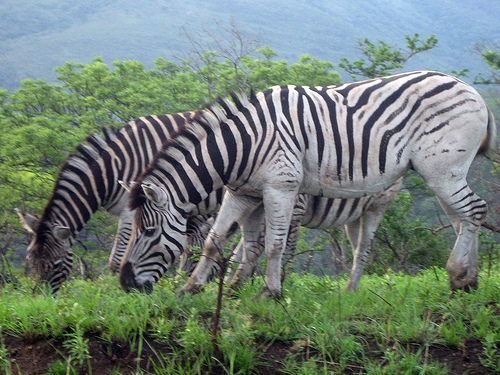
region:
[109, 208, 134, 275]
the black and white leg of a zebra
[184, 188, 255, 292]
the black and white leg of a zebra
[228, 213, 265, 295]
the black and white leg of a zebra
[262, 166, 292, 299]
the black and white leg of a zebra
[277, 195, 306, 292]
the black and white leg of a zebra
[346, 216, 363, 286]
the black and white leg of a zebra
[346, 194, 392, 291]
the black and white leg of a zebra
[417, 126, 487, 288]
the black and white leg of a zebra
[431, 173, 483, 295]
the black and white leg of a zebra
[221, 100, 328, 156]
stripes on a zebra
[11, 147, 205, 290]
two zebra heads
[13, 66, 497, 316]
two zebras eating grass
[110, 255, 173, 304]
zebra mouth grazing in a field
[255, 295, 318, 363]
grass growing in a field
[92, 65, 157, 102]
green leaves on a tree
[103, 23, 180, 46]
grass on the side of a mountain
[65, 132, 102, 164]
striped mane of a zebra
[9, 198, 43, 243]
ear on a horse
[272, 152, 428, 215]
the nearly unstriped belly of a mountain zebra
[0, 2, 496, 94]
a densely treed mountainside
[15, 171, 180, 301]
three zebra grazing in the tall weeds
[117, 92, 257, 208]
mane on the forehead is black while down the neck it is striped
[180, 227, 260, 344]
a root sticks up from the soil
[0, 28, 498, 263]
light green leaved trees set the backdrop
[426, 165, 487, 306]
rear leg is lifted up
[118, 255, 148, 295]
zebra's nose is entirely black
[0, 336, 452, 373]
patches of bare soil among the weeds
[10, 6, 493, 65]
a mountain is in the background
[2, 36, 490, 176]
trees are behind the herd of zebras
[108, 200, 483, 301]
several zebra legs are visible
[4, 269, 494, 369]
the ground is covered in grass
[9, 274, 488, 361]
the grass is green in color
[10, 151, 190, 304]
two of the zebras heads are visible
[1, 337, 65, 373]
some dirt is on the ground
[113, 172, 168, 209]
the zebras ears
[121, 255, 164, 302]
the zebras mouth is on the grass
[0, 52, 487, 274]
two zebras grazing in field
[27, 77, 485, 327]
two zebras eating grass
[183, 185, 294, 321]
white front legs of zebra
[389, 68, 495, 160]
white back body of zebra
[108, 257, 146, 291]
black snout of zebra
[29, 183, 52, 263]
black mane on zebra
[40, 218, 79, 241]
white and black ears of zebra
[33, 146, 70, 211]
black and white mane of zebra